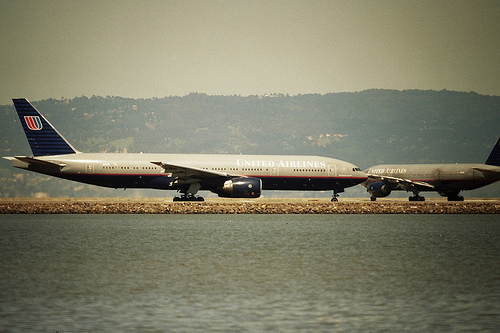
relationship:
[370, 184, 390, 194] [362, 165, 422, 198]
engine on left wing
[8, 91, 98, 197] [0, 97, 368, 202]
tail wing on plane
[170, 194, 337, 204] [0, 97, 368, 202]
landing gear on plane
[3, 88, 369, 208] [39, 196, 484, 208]
airplanes on airstrip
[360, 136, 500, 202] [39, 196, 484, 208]
airplane on airstrip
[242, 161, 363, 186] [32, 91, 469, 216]
red stripe on plane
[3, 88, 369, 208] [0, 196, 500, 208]
airplanes on airstrip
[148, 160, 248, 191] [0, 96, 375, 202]
wing on jet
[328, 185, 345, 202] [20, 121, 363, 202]
nose-gear on jet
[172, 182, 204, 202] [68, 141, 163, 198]
landing gear on a rear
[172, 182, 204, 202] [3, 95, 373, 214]
landing gear on a jet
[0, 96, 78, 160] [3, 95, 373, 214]
tail-fin on a jet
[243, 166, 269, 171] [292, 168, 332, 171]
windows on a windows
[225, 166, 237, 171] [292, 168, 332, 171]
windows on a windows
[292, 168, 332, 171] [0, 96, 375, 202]
windows on a jet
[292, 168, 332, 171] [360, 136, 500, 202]
windows on a airplane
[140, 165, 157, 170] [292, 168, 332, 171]
windows on a windows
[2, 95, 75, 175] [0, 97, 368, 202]
tail of a plane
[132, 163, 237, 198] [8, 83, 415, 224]
wing on a plane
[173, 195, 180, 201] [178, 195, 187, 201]
wheel under a wheel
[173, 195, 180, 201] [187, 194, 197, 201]
wheel under a wheel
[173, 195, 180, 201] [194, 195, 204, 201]
wheel under a wheel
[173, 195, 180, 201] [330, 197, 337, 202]
wheel under a wheel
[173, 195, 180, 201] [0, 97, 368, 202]
wheel under a plane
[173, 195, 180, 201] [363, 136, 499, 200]
wheel under a plane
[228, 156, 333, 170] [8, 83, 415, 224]
white writing on side of plane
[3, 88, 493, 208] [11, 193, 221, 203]
airplanes on grass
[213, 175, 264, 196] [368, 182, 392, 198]
plane engine on side of engine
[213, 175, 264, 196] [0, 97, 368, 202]
plane engine on side of plane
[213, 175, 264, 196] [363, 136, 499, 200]
plane engine on side of plane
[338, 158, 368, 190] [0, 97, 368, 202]
nose of plane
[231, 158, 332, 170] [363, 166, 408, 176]
words on side of words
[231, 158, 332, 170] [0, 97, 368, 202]
words on side of plane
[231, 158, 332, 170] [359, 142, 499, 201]
words on side of plane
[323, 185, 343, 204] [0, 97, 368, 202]
wheel on bottom of plane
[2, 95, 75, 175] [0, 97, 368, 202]
tail of plane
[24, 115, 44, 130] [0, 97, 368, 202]
logo on plane